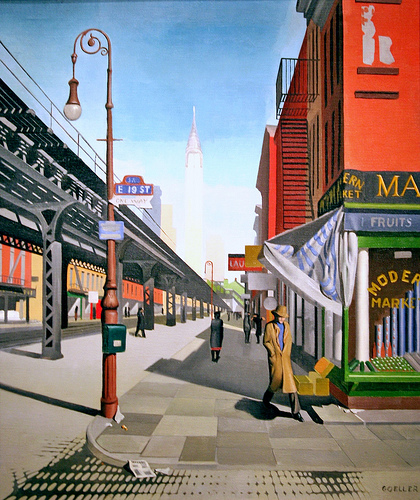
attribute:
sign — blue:
[99, 219, 124, 241]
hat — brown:
[271, 306, 292, 318]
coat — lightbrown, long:
[264, 318, 297, 391]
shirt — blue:
[275, 321, 286, 346]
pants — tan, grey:
[289, 392, 301, 414]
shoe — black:
[295, 411, 304, 424]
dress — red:
[210, 345, 221, 353]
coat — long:
[208, 316, 223, 346]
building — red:
[276, 2, 418, 373]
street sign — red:
[110, 176, 152, 197]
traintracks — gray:
[1, 78, 230, 345]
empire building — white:
[186, 103, 203, 263]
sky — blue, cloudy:
[2, 2, 286, 153]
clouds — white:
[159, 181, 271, 266]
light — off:
[66, 82, 82, 119]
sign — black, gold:
[316, 166, 418, 216]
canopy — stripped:
[258, 210, 345, 314]